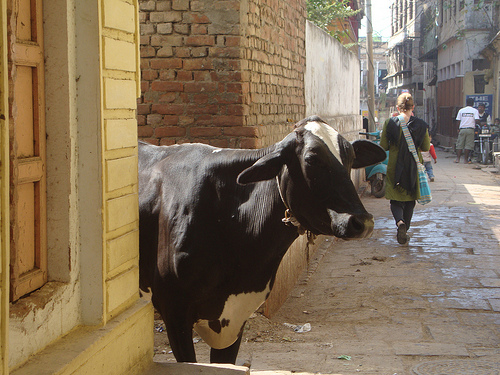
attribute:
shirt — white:
[449, 107, 484, 130]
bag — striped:
[392, 110, 433, 205]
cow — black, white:
[140, 112, 389, 365]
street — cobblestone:
[156, 141, 498, 370]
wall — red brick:
[143, 0, 306, 146]